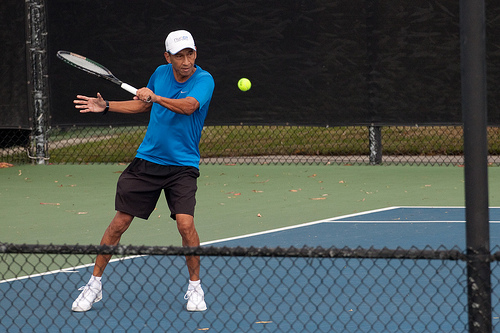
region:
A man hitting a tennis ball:
[45, 16, 277, 235]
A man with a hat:
[129, 24, 210, 108]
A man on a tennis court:
[65, 15, 264, 329]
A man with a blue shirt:
[117, 20, 223, 186]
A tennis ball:
[224, 63, 267, 110]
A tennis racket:
[45, 33, 155, 111]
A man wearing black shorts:
[80, 18, 230, 228]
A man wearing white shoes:
[46, 10, 236, 325]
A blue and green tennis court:
[55, 170, 490, 312]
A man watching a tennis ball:
[30, 17, 274, 322]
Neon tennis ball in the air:
[231, 71, 256, 91]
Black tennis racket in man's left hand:
[47, 41, 137, 91]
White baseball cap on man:
[158, 30, 203, 55]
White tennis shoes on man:
[68, 271, 211, 319]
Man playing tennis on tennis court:
[53, 30, 223, 311]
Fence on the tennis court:
[0, 238, 497, 329]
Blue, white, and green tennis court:
[212, 166, 462, 242]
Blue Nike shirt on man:
[137, 67, 212, 168]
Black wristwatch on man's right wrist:
[100, 95, 112, 115]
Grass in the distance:
[208, 125, 370, 153]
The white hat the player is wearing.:
[161, 27, 199, 57]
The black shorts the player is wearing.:
[115, 152, 206, 219]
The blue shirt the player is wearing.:
[133, 55, 215, 174]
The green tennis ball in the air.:
[232, 71, 252, 92]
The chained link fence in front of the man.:
[3, 235, 499, 330]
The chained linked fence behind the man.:
[4, 5, 499, 168]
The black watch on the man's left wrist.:
[101, 94, 114, 111]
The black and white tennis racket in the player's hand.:
[54, 47, 154, 106]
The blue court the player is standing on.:
[12, 170, 497, 330]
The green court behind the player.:
[7, 149, 499, 256]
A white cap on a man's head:
[147, 21, 208, 60]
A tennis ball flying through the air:
[233, 65, 264, 100]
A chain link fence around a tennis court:
[240, 13, 413, 159]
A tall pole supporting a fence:
[440, 11, 492, 261]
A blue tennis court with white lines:
[255, 190, 480, 310]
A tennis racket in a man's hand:
[52, 37, 164, 118]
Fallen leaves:
[225, 172, 342, 197]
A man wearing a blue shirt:
[130, 60, 215, 162]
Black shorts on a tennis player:
[114, 157, 215, 228]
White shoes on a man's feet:
[60, 260, 217, 318]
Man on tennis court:
[46, 211, 445, 329]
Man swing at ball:
[55, 27, 278, 114]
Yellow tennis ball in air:
[232, 67, 268, 101]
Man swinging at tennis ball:
[53, 31, 281, 132]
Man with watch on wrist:
[93, 92, 118, 127]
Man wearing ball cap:
[157, 18, 201, 61]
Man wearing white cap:
[159, 30, 210, 60]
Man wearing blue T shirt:
[142, 59, 224, 186]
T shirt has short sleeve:
[182, 74, 224, 115]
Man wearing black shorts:
[109, 145, 221, 231]